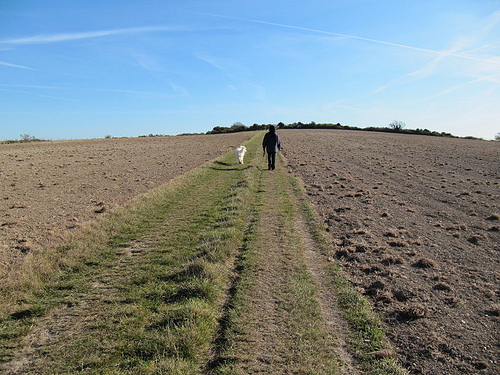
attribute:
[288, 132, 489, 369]
field — in the picture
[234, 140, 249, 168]
dog — in the picture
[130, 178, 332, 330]
road — in the picture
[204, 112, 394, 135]
trees — in the picture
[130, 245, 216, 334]
grass — in the picture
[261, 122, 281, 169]
person — walking 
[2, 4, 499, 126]
sky — blue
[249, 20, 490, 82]
contrail — jet contrail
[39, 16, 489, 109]
sky — blue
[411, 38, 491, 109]
clouds — in the picture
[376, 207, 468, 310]
dirt clumps — in the picture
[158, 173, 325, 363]
grass — green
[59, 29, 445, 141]
sky — in the picture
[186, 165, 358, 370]
track — worn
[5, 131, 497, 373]
field — dry, in the picture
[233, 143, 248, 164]
animal — in the picture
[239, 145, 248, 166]
dog — white 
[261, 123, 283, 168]
person — in the picture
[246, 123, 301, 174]
person — in the picture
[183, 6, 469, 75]
lines — whispy, white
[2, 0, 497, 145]
sky — in the picture, blue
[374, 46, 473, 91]
lines — white, whispy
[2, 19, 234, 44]
lines — white, whispy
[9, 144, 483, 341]
land — in the picture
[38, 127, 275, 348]
field — in the picture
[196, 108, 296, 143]
trees — in the picture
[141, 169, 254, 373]
grass — dry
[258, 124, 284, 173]
man — in the picture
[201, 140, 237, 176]
shadow — in the picture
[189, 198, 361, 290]
land — in the picture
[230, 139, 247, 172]
dog — white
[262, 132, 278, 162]
outfit — black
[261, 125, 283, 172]
man — walking